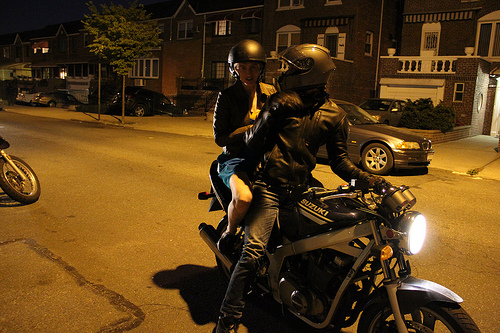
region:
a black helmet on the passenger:
[226, 40, 265, 76]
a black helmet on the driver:
[284, 44, 339, 79]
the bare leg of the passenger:
[220, 163, 252, 247]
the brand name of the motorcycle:
[298, 196, 330, 221]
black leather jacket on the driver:
[242, 98, 369, 190]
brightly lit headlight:
[407, 211, 425, 256]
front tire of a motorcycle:
[354, 289, 482, 331]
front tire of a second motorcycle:
[0, 151, 42, 203]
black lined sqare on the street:
[2, 234, 146, 331]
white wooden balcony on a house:
[382, 48, 479, 75]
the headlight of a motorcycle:
[388, 208, 443, 263]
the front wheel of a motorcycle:
[0, 147, 47, 205]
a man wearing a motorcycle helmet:
[269, 33, 347, 107]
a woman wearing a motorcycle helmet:
[220, 30, 275, 100]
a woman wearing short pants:
[200, 121, 274, 263]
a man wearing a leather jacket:
[230, 79, 402, 222]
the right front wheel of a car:
[358, 139, 396, 174]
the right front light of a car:
[392, 131, 424, 158]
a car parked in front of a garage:
[360, 73, 445, 133]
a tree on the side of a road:
[70, 5, 155, 135]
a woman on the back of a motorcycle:
[206, 21, 286, 267]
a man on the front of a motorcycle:
[218, 40, 397, 331]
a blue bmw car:
[311, 91, 435, 180]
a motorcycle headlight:
[400, 211, 431, 256]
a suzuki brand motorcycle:
[198, 143, 486, 329]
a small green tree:
[81, 0, 167, 129]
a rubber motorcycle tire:
[1, 147, 45, 210]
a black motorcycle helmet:
[223, 33, 270, 79]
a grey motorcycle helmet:
[278, 37, 335, 90]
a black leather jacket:
[248, 75, 394, 200]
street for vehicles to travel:
[43, 133, 180, 240]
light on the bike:
[402, 210, 429, 250]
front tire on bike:
[362, 280, 477, 331]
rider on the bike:
[268, 44, 372, 294]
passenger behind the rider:
[211, 36, 257, 208]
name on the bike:
[299, 195, 331, 220]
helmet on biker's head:
[277, 44, 342, 96]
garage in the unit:
[383, 78, 444, 117]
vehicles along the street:
[13, 73, 198, 119]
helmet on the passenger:
[229, 35, 264, 76]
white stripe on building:
[402, 13, 409, 24]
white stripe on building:
[406, 14, 414, 23]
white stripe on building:
[410, 13, 417, 23]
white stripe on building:
[419, 13, 426, 23]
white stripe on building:
[466, 10, 473, 21]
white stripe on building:
[461, 8, 468, 20]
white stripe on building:
[457, 11, 463, 20]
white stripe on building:
[448, 10, 455, 20]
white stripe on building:
[440, 12, 445, 21]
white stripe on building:
[431, 11, 436, 23]